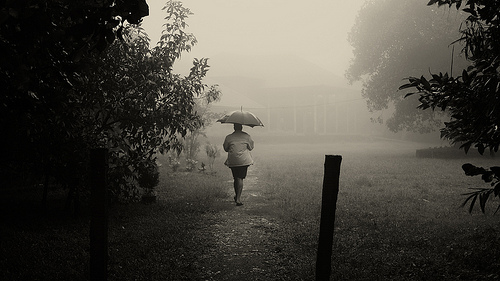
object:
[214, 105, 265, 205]
woman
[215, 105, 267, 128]
umbrella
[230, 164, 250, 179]
skirt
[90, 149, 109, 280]
post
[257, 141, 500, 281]
grass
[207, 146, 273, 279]
path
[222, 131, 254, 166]
coat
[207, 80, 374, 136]
building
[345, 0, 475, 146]
tree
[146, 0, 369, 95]
sky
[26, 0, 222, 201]
tree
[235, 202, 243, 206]
shoe